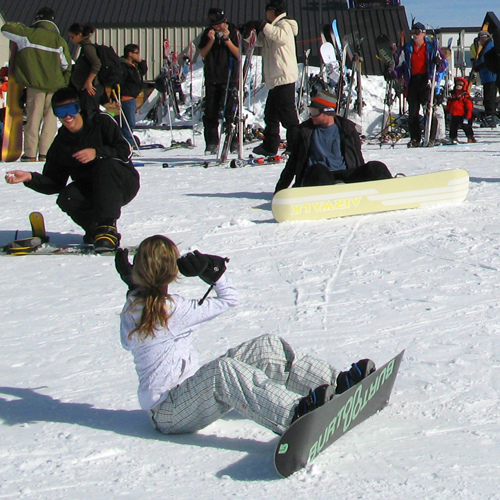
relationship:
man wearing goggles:
[9, 89, 141, 254] [55, 103, 79, 120]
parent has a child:
[391, 22, 446, 146] [446, 79, 476, 143]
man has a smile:
[9, 89, 141, 254] [68, 118, 74, 124]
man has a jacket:
[2, 8, 72, 162] [2, 18, 74, 92]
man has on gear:
[9, 89, 141, 254] [54, 98, 122, 253]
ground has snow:
[0, 57, 499, 500] [0, 56, 497, 500]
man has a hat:
[2, 8, 72, 162] [37, 6, 56, 22]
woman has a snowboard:
[114, 235, 406, 477] [274, 349, 405, 476]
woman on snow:
[114, 235, 406, 477] [0, 56, 497, 500]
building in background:
[2, 1, 415, 128] [2, 1, 500, 255]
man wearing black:
[9, 89, 141, 254] [24, 116, 141, 226]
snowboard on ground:
[274, 349, 405, 476] [0, 57, 499, 500]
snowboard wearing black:
[274, 349, 405, 476] [24, 116, 141, 226]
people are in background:
[6, 3, 500, 475] [2, 1, 500, 255]